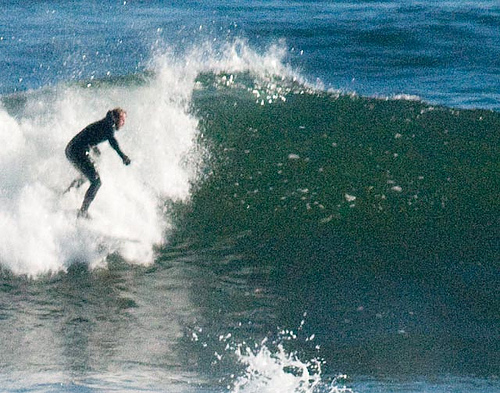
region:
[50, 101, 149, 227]
person riding a surfboard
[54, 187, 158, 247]
white surfboard in the water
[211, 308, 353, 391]
foam splashing up out of the water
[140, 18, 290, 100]
foam splashing up out of the water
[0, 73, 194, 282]
foam splashing up out of the water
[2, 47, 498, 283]
medium sized wave in the ocean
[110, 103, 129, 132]
head of a person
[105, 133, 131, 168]
arm of a person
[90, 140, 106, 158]
arm of a person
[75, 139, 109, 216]
leg of a person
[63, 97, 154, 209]
man in the water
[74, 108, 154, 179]
man in a wetsuit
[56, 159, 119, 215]
legs of the man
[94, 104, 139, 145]
head of the man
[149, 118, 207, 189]
white water in the photo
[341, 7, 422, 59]
still water in the background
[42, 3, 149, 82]
water in the air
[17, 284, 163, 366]
light hitting the water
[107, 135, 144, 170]
arm of the man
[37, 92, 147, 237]
surfer inside white wave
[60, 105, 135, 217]
surfer wearing black wetsuit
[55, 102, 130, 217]
surfer leaning forward with bent knees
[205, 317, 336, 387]
splashing semicircle of white water in front of wave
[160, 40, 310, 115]
white water curving over top of wave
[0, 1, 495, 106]
blue water with darker patches behind wave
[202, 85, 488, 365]
green wall of water over bluer water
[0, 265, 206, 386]
white reflection of water on ocean surface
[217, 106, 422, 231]
white dots on side of wave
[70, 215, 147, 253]
white surfboard in white wave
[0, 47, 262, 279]
White top of the wave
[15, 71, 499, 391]
A huge wave in the ocean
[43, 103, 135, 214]
Guy surfing in the ocean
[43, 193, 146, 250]
White surfboard that is barely visible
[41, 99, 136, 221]
Guy in a black swimsuit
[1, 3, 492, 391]
Green and blue water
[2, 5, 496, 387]
A large body of water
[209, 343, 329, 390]
A splash in the ocean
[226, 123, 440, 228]
White studs in the ocean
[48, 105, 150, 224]
man balancing on surfboard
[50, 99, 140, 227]
a surfer on the water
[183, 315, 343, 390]
a splash of white foam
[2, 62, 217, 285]
a huge splash of foam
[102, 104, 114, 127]
a hood on his jacket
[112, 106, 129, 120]
his hair is blonde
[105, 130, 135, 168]
his hand is outstretched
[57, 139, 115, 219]
his knees are bent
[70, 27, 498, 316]
a wave of water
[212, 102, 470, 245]
specks of foam on the waves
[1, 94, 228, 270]
the foam is white